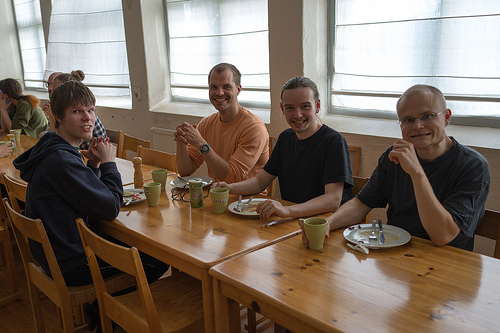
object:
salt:
[130, 156, 144, 187]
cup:
[298, 217, 329, 249]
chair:
[75, 218, 205, 333]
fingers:
[298, 219, 305, 231]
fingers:
[325, 228, 331, 238]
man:
[174, 62, 270, 194]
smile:
[214, 95, 227, 101]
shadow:
[375, 237, 483, 332]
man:
[11, 82, 167, 277]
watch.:
[199, 143, 212, 155]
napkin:
[346, 242, 370, 255]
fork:
[368, 219, 377, 245]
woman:
[45, 71, 108, 149]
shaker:
[187, 178, 204, 208]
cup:
[143, 182, 162, 206]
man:
[301, 84, 490, 252]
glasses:
[397, 108, 448, 126]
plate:
[227, 198, 282, 216]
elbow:
[428, 213, 464, 245]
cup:
[151, 169, 168, 191]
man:
[211, 77, 356, 221]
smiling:
[292, 119, 307, 125]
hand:
[300, 218, 330, 248]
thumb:
[324, 223, 331, 239]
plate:
[170, 175, 214, 189]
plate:
[121, 188, 147, 205]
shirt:
[186, 107, 269, 184]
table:
[87, 173, 336, 332]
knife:
[264, 219, 282, 227]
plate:
[342, 222, 410, 248]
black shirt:
[354, 135, 491, 252]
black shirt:
[261, 123, 353, 205]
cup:
[210, 187, 230, 214]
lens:
[402, 117, 415, 125]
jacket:
[11, 132, 124, 272]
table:
[208, 224, 498, 330]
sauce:
[381, 232, 395, 242]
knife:
[378, 219, 385, 245]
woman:
[214, 77, 353, 222]